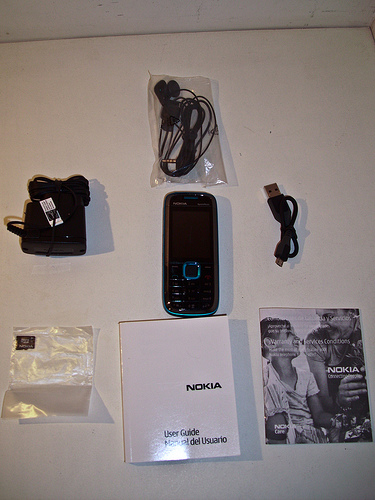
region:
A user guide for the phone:
[117, 323, 239, 459]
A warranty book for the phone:
[259, 308, 370, 446]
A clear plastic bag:
[4, 326, 91, 388]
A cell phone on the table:
[161, 194, 219, 314]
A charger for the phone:
[9, 178, 90, 254]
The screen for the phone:
[167, 207, 212, 261]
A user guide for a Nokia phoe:
[118, 321, 240, 454]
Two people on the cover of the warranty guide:
[262, 309, 357, 442]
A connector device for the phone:
[260, 183, 298, 267]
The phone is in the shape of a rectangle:
[163, 191, 219, 315]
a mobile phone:
[162, 196, 229, 323]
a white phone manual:
[112, 312, 236, 463]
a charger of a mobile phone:
[7, 169, 104, 255]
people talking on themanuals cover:
[260, 310, 365, 442]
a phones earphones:
[143, 82, 233, 179]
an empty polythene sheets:
[17, 328, 92, 423]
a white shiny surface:
[35, 73, 119, 140]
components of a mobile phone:
[7, 77, 371, 462]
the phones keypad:
[167, 264, 220, 315]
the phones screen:
[172, 210, 213, 261]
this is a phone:
[153, 193, 224, 301]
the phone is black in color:
[181, 208, 198, 256]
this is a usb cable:
[254, 175, 300, 260]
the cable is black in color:
[282, 198, 312, 257]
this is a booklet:
[256, 304, 372, 419]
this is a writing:
[171, 375, 228, 403]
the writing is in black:
[172, 374, 252, 417]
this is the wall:
[256, 46, 346, 114]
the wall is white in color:
[274, 47, 368, 137]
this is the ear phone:
[154, 86, 193, 158]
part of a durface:
[220, 57, 255, 115]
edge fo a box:
[172, 449, 187, 462]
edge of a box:
[199, 447, 225, 469]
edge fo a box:
[165, 440, 195, 475]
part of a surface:
[290, 462, 316, 493]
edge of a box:
[190, 438, 217, 476]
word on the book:
[179, 370, 231, 408]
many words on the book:
[159, 368, 230, 454]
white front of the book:
[157, 328, 222, 361]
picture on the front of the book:
[258, 302, 363, 423]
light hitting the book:
[155, 424, 192, 473]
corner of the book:
[229, 441, 252, 469]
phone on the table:
[149, 189, 235, 311]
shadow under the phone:
[223, 198, 241, 237]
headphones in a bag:
[155, 70, 223, 161]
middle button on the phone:
[177, 254, 204, 290]